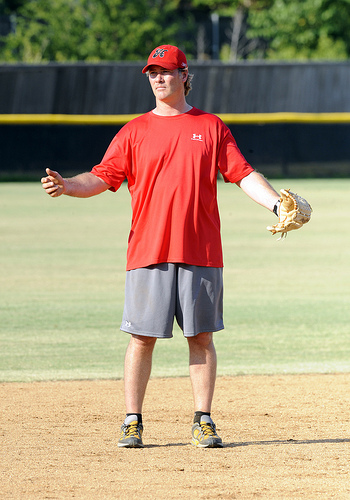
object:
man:
[40, 46, 313, 452]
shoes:
[117, 411, 144, 453]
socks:
[193, 412, 211, 424]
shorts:
[119, 263, 223, 340]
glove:
[268, 189, 314, 236]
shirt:
[89, 107, 254, 270]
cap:
[141, 43, 188, 73]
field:
[0, 176, 350, 500]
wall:
[0, 61, 348, 114]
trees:
[218, 1, 350, 61]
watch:
[273, 198, 280, 217]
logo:
[152, 48, 169, 59]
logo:
[191, 134, 203, 143]